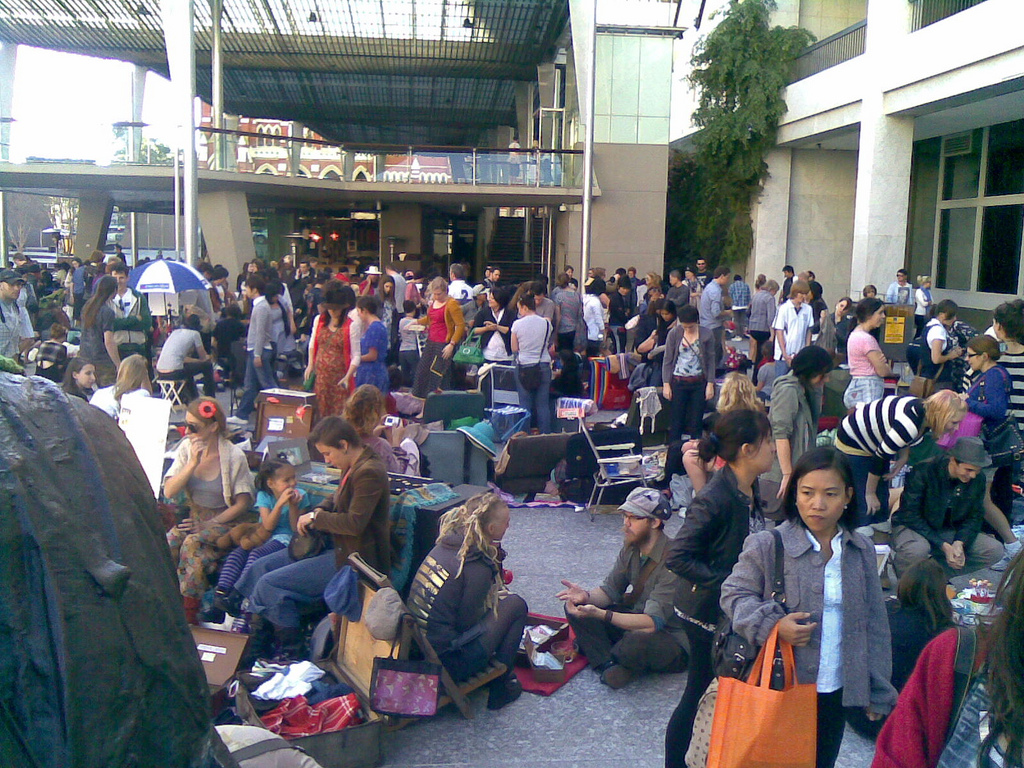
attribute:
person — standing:
[261, 275, 301, 358]